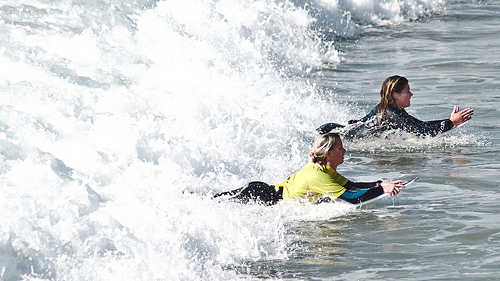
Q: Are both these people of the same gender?
A: Yes, all the people are female.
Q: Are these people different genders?
A: No, all the people are female.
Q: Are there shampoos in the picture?
A: No, there are no shampoos.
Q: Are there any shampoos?
A: No, there are no shampoos.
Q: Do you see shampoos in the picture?
A: No, there are no shampoos.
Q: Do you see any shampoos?
A: No, there are no shampoos.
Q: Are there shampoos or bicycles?
A: No, there are no shampoos or bicycles.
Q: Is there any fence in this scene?
A: No, there are no fences.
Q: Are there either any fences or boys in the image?
A: No, there are no fences or boys.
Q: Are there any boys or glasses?
A: No, there are no boys or glasses.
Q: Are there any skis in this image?
A: No, there are no skis.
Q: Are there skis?
A: No, there are no skis.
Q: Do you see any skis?
A: No, there are no skis.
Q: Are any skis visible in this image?
A: No, there are no skis.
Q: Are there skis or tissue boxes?
A: No, there are no skis or tissue boxes.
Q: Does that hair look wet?
A: Yes, the hair is wet.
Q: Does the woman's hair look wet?
A: Yes, the hair is wet.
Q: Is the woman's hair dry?
A: No, the hair is wet.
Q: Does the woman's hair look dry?
A: No, the hair is wet.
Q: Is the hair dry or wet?
A: The hair is wet.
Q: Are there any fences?
A: No, there are no fences.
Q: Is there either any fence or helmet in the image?
A: No, there are no fences or helmets.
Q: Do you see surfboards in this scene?
A: Yes, there is a surfboard.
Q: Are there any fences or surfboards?
A: Yes, there is a surfboard.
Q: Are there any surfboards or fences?
A: Yes, there is a surfboard.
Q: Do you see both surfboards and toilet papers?
A: No, there is a surfboard but no toilet papers.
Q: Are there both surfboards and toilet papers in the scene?
A: No, there is a surfboard but no toilet papers.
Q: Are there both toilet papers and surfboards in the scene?
A: No, there is a surfboard but no toilet papers.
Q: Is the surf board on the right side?
A: Yes, the surf board is on the right of the image.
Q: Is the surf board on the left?
A: No, the surf board is on the right of the image.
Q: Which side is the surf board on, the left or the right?
A: The surf board is on the right of the image.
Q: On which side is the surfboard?
A: The surfboard is on the right of the image.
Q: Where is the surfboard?
A: The surfboard is in the water.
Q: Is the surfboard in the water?
A: Yes, the surfboard is in the water.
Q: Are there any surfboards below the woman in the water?
A: Yes, there is a surfboard below the woman.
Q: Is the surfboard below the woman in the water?
A: Yes, the surfboard is below the woman.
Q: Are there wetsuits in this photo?
A: Yes, there is a wetsuit.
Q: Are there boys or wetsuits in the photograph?
A: Yes, there is a wetsuit.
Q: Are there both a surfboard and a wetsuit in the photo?
A: Yes, there are both a wetsuit and a surfboard.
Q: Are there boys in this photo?
A: No, there are no boys.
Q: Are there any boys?
A: No, there are no boys.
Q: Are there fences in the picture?
A: No, there are no fences.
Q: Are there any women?
A: Yes, there is a woman.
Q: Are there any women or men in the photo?
A: Yes, there is a woman.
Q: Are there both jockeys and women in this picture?
A: No, there is a woman but no jockeys.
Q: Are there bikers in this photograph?
A: No, there are no bikers.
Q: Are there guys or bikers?
A: No, there are no bikers or guys.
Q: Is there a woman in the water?
A: Yes, there is a woman in the water.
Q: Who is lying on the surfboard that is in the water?
A: The woman is lying on the surf board.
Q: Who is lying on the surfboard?
A: The woman is lying on the surf board.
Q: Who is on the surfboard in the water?
A: The woman is on the surfboard.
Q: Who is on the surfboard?
A: The woman is on the surfboard.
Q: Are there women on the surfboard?
A: Yes, there is a woman on the surfboard.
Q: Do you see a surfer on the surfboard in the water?
A: No, there is a woman on the surfboard.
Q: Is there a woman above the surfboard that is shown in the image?
A: Yes, there is a woman above the surfboard.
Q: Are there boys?
A: No, there are no boys.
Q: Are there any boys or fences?
A: No, there are no boys or fences.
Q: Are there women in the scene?
A: Yes, there is a woman.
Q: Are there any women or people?
A: Yes, there is a woman.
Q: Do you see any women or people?
A: Yes, there is a woman.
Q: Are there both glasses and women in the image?
A: No, there is a woman but no glasses.